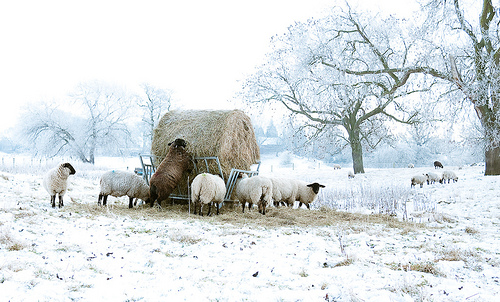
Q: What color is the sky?
A: White.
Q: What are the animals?
A: Sheep.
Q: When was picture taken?
A: Winter.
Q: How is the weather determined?
A: Snow.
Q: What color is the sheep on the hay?
A: Brown.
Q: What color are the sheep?
A: Black and white.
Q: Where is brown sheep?
A: On the hay.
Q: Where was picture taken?
A: At a farm.